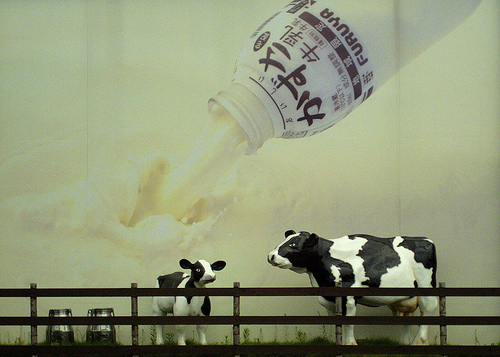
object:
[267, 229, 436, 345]
cow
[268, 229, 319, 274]
head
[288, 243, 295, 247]
eye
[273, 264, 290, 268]
mouth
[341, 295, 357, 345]
leg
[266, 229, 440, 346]
body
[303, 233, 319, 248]
ear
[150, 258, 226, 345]
cow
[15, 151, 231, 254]
milk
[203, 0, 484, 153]
bottle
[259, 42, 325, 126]
character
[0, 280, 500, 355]
fence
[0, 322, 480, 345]
grass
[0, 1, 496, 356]
billboard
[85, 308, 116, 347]
tub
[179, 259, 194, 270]
ear